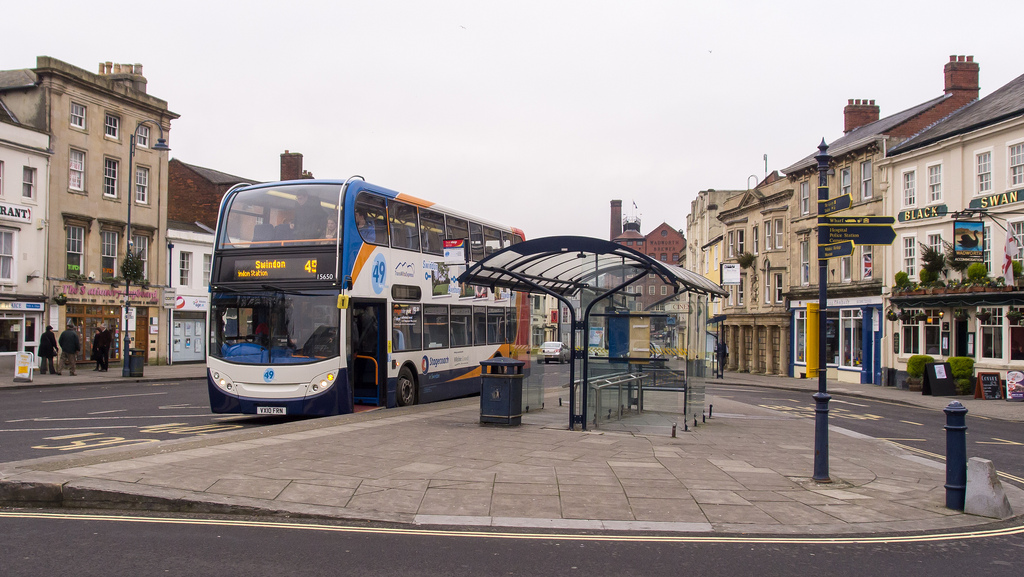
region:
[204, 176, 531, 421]
a double decker bus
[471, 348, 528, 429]
a blue garbage can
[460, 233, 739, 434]
a bus waiting area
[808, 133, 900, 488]
a blue and yellow street sign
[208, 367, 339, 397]
headlights of a bus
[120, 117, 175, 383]
a tall light pole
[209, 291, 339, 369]
driver's front window of a bus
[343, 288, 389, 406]
door of a bus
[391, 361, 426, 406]
wheel on a bus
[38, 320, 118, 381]
people standing on a sidewalk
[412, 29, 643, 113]
thick clouds in sky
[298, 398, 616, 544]
bus stop is brown stone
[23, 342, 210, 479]
road is dark grey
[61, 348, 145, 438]
white lines on road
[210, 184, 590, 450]
blue white and orange bus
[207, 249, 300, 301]
orange LCD with destination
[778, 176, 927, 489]
black pole with signs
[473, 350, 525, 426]
Black trash can on the ground.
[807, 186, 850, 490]
Large black pole in the sidewalk.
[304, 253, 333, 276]
Orange numbers lit up on the bus.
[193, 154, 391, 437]
Front of a blue and white bus.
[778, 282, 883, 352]
Blue and white paint on the building.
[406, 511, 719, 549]
Group of white painted blocks.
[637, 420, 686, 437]
Small black stands in the ground.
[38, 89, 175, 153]
Three windows on the front of the building.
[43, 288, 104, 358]
People walking on the sidewalk.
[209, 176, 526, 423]
a double decker touring bus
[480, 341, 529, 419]
a trash receptacle by a bus stop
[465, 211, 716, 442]
shelter at a bus stop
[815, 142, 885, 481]
sign tells the street name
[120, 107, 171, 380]
a high goose neck street light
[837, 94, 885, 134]
wide red brick chimney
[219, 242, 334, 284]
destination and route number on the bus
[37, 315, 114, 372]
three people gather on the sidewalk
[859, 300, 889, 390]
blue trim around a door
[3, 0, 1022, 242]
cloud cover in sky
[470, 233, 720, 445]
arched roof of bus shelter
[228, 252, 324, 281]
yellow words on display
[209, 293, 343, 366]
windshield on front of bus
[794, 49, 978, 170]
chimneys on building roof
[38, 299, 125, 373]
people in front of store window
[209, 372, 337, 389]
glowing headlights of bus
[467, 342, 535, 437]
trash can by bus stop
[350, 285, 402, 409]
open door on bus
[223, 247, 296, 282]
destination on a bus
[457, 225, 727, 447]
bus stop on a traffic circle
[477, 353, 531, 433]
blue colored trash bin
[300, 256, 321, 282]
number 49 on a bus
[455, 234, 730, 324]
covered area ofa bus stop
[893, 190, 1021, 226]
sign for the black sway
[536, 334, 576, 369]
silver car on the road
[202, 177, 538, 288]
top level of the bus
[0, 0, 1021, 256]
clear grey colored sky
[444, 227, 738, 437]
bus stop bench with roof